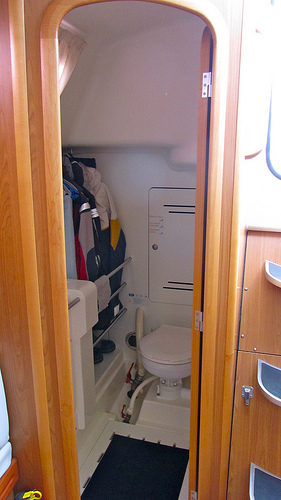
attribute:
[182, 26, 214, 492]
door — wooden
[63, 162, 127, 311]
clothes — hanging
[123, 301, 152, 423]
pipes — white, plastic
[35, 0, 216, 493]
door — open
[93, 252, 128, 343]
bars — metal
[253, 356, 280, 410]
shelf — curved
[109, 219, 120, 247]
design — gold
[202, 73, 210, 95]
hinge — silver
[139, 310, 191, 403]
toilet — white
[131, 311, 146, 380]
pipe — water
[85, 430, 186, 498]
mat — black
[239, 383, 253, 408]
handle — metal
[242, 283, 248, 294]
rivet — silver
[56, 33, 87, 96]
curtain — white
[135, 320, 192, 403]
toilet — white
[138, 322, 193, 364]
toilet seat — closed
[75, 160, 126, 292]
jacket — blue, yellow, white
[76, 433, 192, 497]
mat — black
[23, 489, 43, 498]
object — yellow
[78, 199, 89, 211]
stripes — silver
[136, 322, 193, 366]
lid — white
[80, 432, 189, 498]
rug — black, dark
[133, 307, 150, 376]
pipe — white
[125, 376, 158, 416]
pipe — white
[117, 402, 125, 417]
valve — red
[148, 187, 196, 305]
access panel — white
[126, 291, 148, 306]
sticker — white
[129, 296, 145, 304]
lettering — blue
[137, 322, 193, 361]
lid — white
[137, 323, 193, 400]
toilet — small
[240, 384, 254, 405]
door handle — silver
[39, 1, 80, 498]
door frame — light brown, wooden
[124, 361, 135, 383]
valve — red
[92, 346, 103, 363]
boot — big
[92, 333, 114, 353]
boot — big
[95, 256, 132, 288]
bar — silver, metal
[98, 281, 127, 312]
bar — silver, metal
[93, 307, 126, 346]
bar — silver, metal